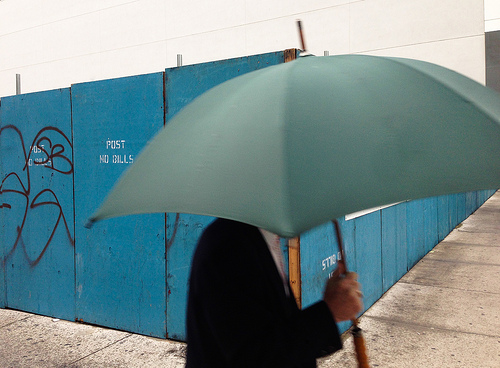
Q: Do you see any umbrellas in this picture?
A: Yes, there is an umbrella.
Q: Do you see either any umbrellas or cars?
A: Yes, there is an umbrella.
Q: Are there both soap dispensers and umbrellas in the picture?
A: No, there is an umbrella but no soap dispensers.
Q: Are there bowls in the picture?
A: No, there are no bowls.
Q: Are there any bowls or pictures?
A: No, there are no bowls or pictures.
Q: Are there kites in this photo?
A: No, there are no kites.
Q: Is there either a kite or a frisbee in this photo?
A: No, there are no kites or frisbees.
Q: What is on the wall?
A: The graffiti is on the wall.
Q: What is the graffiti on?
A: The graffiti is on the wall.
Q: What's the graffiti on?
A: The graffiti is on the wall.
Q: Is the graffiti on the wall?
A: Yes, the graffiti is on the wall.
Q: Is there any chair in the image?
A: No, there are no chairs.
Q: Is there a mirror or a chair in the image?
A: No, there are no chairs or mirrors.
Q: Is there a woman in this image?
A: No, there are no women.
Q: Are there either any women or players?
A: No, there are no women or players.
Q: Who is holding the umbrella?
A: The man is holding the umbrella.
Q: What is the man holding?
A: The man is holding the umbrella.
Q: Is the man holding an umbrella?
A: Yes, the man is holding an umbrella.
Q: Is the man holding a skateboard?
A: No, the man is holding an umbrella.